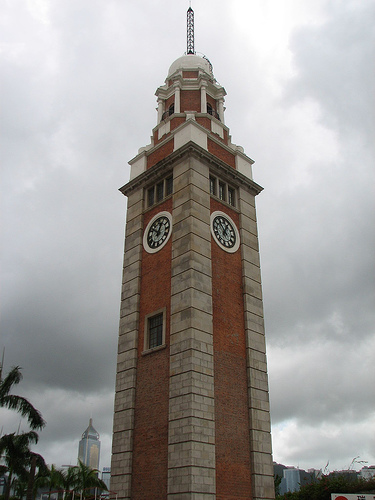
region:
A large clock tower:
[109, 7, 275, 498]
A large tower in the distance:
[77, 410, 100, 473]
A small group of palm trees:
[0, 343, 107, 498]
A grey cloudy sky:
[0, 0, 373, 475]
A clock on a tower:
[209, 208, 239, 254]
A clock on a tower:
[141, 210, 172, 253]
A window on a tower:
[142, 308, 166, 353]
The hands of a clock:
[215, 221, 232, 235]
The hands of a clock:
[148, 217, 164, 236]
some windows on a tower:
[145, 173, 173, 204]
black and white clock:
[135, 206, 182, 260]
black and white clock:
[192, 201, 244, 251]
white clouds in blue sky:
[288, 140, 325, 198]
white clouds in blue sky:
[262, 240, 338, 281]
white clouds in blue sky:
[312, 299, 345, 360]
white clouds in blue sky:
[11, 202, 58, 256]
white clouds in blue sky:
[43, 286, 76, 329]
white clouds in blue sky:
[36, 111, 111, 193]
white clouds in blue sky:
[36, 41, 112, 101]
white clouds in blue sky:
[270, 36, 325, 85]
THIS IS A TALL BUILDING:
[104, 6, 273, 498]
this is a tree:
[71, 460, 105, 497]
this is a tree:
[61, 461, 88, 499]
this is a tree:
[3, 425, 37, 499]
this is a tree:
[0, 358, 48, 497]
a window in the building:
[128, 308, 183, 366]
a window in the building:
[207, 168, 219, 196]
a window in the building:
[216, 174, 226, 204]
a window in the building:
[138, 173, 172, 206]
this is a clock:
[140, 210, 180, 258]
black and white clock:
[145, 214, 169, 246]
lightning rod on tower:
[186, 7, 195, 53]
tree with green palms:
[2, 430, 47, 497]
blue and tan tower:
[79, 418, 102, 471]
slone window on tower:
[144, 310, 164, 349]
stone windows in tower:
[142, 174, 173, 205]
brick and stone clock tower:
[155, 56, 228, 134]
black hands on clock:
[152, 222, 163, 237]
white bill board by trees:
[331, 492, 373, 498]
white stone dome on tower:
[168, 55, 215, 78]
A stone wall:
[170, 249, 211, 357]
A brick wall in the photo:
[219, 363, 246, 446]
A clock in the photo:
[207, 209, 241, 254]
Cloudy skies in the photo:
[294, 151, 342, 275]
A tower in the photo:
[123, 13, 281, 460]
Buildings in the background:
[49, 429, 114, 480]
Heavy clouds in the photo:
[21, 321, 101, 382]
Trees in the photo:
[16, 451, 91, 499]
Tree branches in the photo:
[19, 433, 92, 489]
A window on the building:
[143, 307, 167, 353]